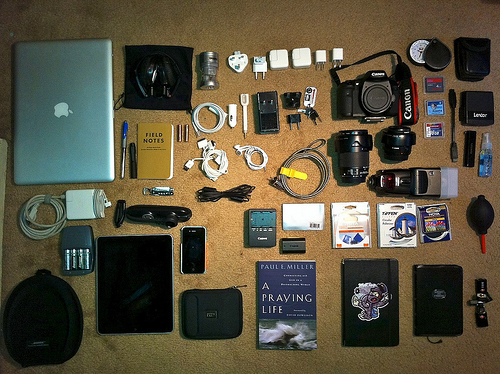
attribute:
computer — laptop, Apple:
[14, 40, 121, 182]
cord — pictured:
[195, 180, 255, 208]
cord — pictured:
[276, 133, 336, 197]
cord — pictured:
[190, 90, 232, 136]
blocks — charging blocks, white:
[269, 47, 345, 69]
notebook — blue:
[134, 119, 175, 183]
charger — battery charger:
[54, 224, 100, 282]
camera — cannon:
[322, 52, 421, 135]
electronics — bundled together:
[5, 26, 499, 371]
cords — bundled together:
[183, 101, 271, 206]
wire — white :
[192, 97, 247, 140]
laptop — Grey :
[12, 36, 119, 186]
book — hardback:
[254, 257, 320, 345]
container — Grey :
[54, 225, 99, 277]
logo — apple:
[48, 97, 77, 122]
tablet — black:
[94, 234, 174, 335]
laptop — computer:
[10, 36, 112, 195]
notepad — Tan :
[137, 110, 172, 177]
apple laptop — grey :
[9, 38, 113, 182]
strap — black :
[328, 48, 419, 125]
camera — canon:
[337, 67, 418, 124]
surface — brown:
[20, 13, 478, 366]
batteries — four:
[59, 244, 97, 274]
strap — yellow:
[273, 160, 316, 189]